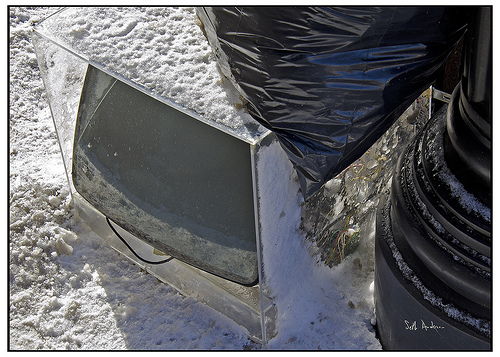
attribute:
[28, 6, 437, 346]
television — small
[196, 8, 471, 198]
trash bag — black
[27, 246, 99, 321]
snow — white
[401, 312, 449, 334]
name — white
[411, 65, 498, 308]
object — black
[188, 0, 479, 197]
plasticbag — black